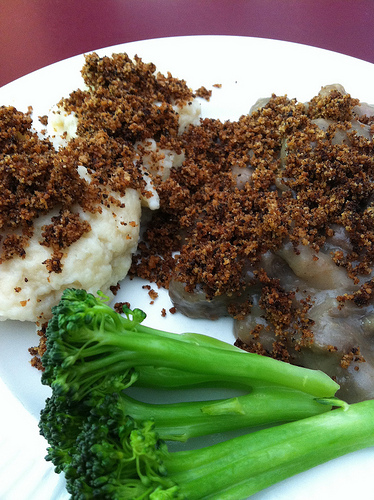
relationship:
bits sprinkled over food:
[332, 352, 352, 366] [18, 92, 358, 310]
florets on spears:
[41, 290, 104, 394] [174, 355, 299, 486]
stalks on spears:
[136, 323, 257, 484] [216, 327, 362, 468]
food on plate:
[220, 110, 331, 308] [3, 358, 17, 404]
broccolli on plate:
[124, 298, 155, 327] [304, 469, 342, 487]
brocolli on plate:
[47, 299, 342, 462] [324, 475, 349, 489]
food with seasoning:
[0, 164, 143, 324] [174, 229, 204, 248]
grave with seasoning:
[328, 305, 342, 331] [280, 184, 340, 207]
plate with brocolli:
[10, 335, 21, 381] [38, 285, 342, 474]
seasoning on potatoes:
[209, 126, 313, 206] [83, 244, 100, 267]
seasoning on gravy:
[209, 126, 313, 206] [314, 293, 327, 324]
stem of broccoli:
[152, 310, 356, 452] [52, 313, 115, 466]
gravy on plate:
[330, 306, 340, 335] [22, 407, 32, 457]